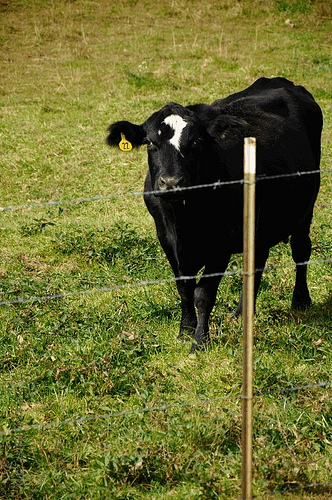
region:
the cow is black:
[96, 98, 273, 389]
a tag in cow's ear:
[96, 99, 136, 181]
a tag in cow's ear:
[80, 106, 141, 156]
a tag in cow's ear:
[97, 95, 163, 202]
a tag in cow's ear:
[99, 116, 161, 164]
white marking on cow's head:
[163, 110, 186, 148]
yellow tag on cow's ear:
[113, 130, 133, 150]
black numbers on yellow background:
[117, 133, 132, 153]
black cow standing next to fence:
[111, 75, 326, 348]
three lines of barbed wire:
[7, 193, 331, 434]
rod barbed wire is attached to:
[236, 133, 260, 497]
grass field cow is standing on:
[7, 4, 331, 499]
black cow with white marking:
[109, 75, 321, 342]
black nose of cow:
[155, 172, 182, 194]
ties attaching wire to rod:
[241, 176, 255, 407]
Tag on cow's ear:
[118, 135, 130, 149]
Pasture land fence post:
[241, 138, 257, 497]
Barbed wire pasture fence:
[0, 191, 148, 199]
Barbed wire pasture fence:
[9, 276, 178, 288]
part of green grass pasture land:
[41, 403, 139, 448]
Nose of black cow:
[154, 176, 187, 192]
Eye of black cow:
[143, 139, 155, 148]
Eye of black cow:
[189, 139, 199, 150]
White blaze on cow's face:
[163, 113, 187, 152]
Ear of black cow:
[205, 117, 247, 144]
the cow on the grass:
[96, 84, 323, 325]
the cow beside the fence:
[88, 78, 327, 327]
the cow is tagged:
[115, 70, 327, 335]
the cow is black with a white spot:
[105, 79, 331, 337]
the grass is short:
[19, 237, 127, 287]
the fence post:
[226, 132, 268, 496]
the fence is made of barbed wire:
[4, 140, 331, 498]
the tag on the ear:
[110, 124, 135, 155]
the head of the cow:
[94, 94, 240, 214]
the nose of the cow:
[157, 173, 187, 194]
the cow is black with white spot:
[89, 68, 328, 330]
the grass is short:
[44, 234, 112, 269]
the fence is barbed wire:
[8, 133, 329, 482]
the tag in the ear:
[99, 113, 139, 159]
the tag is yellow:
[111, 113, 139, 157]